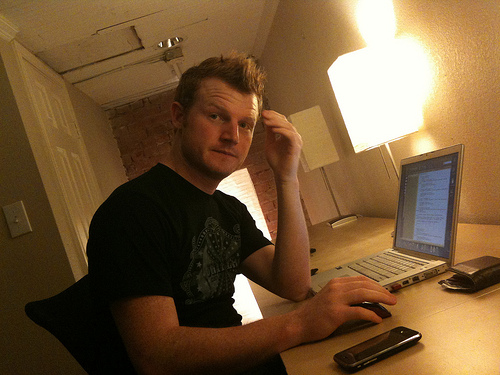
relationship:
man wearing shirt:
[85, 50, 398, 374] [85, 163, 274, 327]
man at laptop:
[85, 50, 398, 374] [307, 143, 464, 297]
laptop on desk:
[307, 143, 464, 297] [244, 213, 500, 369]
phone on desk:
[332, 324, 422, 372] [244, 213, 500, 369]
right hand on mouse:
[300, 274, 398, 340] [328, 304, 391, 338]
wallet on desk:
[438, 254, 500, 294] [244, 213, 500, 369]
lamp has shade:
[328, 44, 401, 182] [325, 44, 421, 157]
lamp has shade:
[286, 105, 359, 230] [284, 101, 340, 175]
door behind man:
[0, 40, 103, 282] [85, 50, 398, 374]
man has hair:
[85, 50, 398, 374] [171, 50, 263, 137]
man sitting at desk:
[85, 50, 398, 374] [244, 213, 500, 369]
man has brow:
[85, 50, 398, 374] [206, 100, 231, 114]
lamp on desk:
[328, 44, 401, 182] [244, 213, 500, 369]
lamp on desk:
[286, 105, 359, 230] [244, 213, 500, 369]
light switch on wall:
[1, 200, 31, 240] [1, 59, 89, 373]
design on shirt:
[176, 213, 244, 308] [85, 163, 274, 327]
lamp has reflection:
[328, 44, 401, 182] [351, 1, 435, 160]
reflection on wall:
[351, 1, 435, 160] [261, 3, 498, 224]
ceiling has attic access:
[0, 1, 279, 109] [71, 58, 180, 109]